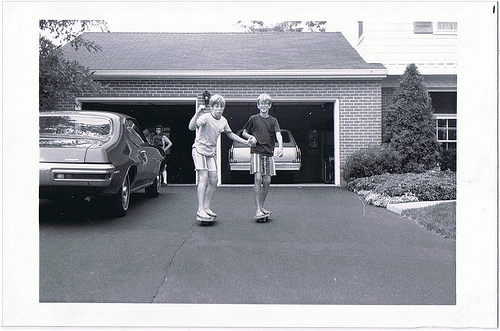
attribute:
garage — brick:
[33, 29, 398, 193]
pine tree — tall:
[377, 51, 449, 175]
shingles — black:
[47, 29, 383, 69]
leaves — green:
[386, 62, 440, 174]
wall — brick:
[349, 86, 364, 118]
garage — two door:
[72, 92, 342, 187]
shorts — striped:
[251, 154, 282, 176]